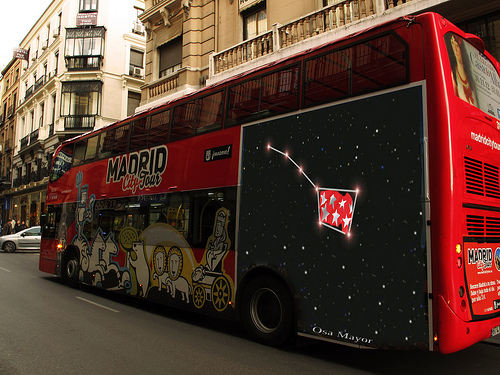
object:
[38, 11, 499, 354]
bus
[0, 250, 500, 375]
street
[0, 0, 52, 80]
clouds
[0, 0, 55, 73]
sky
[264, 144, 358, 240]
dipper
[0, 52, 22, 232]
buildings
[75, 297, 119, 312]
line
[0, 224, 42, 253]
car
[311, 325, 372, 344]
osa mayor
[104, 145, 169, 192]
madrid city tour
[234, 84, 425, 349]
mural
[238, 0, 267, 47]
balconies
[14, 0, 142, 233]
apartments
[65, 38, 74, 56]
curtains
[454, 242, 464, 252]
light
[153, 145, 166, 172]
writing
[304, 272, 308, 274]
constellation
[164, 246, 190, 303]
lions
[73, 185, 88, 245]
gladiator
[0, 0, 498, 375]
scene